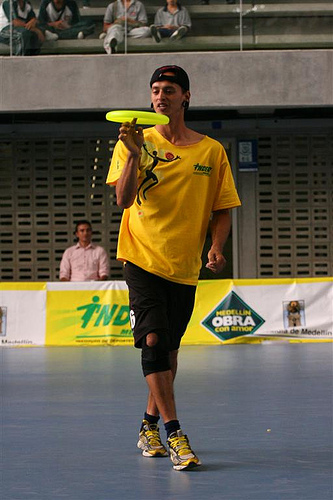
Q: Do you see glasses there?
A: No, there are no glasses.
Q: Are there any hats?
A: Yes, there is a hat.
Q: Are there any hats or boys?
A: Yes, there is a hat.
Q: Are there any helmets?
A: No, there are no helmets.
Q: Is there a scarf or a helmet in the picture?
A: No, there are no helmets or scarves.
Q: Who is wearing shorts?
A: The man is wearing shorts.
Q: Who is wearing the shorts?
A: The man is wearing shorts.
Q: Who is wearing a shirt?
A: The man is wearing a shirt.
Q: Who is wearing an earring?
A: The man is wearing an earring.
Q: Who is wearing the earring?
A: The man is wearing an earring.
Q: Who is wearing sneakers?
A: The man is wearing sneakers.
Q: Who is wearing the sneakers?
A: The man is wearing sneakers.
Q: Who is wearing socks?
A: The man is wearing socks.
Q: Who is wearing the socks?
A: The man is wearing socks.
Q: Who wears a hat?
A: The man wears a hat.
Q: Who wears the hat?
A: The man wears a hat.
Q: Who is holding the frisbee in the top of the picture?
A: The man is holding the frisbee.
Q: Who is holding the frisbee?
A: The man is holding the frisbee.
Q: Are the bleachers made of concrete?
A: Yes, the bleachers are made of concrete.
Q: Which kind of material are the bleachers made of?
A: The bleachers are made of cement.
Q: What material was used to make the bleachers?
A: The bleachers are made of cement.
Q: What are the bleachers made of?
A: The bleachers are made of concrete.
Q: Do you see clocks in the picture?
A: No, there are no clocks.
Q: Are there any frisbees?
A: Yes, there is a frisbee.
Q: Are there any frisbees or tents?
A: Yes, there is a frisbee.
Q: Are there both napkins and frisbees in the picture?
A: No, there is a frisbee but no napkins.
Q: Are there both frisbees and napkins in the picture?
A: No, there is a frisbee but no napkins.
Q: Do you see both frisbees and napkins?
A: No, there is a frisbee but no napkins.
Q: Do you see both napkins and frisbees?
A: No, there is a frisbee but no napkins.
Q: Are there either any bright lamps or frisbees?
A: Yes, there is a bright frisbee.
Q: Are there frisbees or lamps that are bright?
A: Yes, the frisbee is bright.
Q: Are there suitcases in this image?
A: No, there are no suitcases.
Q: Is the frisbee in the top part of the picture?
A: Yes, the frisbee is in the top of the image.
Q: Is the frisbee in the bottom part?
A: No, the frisbee is in the top of the image.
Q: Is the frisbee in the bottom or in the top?
A: The frisbee is in the top of the image.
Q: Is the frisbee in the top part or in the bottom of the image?
A: The frisbee is in the top of the image.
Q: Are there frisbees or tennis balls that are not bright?
A: No, there is a frisbee but it is bright.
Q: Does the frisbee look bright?
A: Yes, the frisbee is bright.